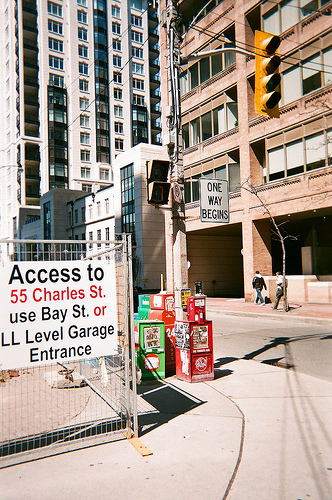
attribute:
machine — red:
[170, 279, 216, 385]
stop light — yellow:
[251, 28, 281, 120]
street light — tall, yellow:
[239, 21, 304, 134]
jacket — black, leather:
[250, 274, 268, 291]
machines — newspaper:
[135, 289, 220, 388]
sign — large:
[24, 257, 123, 387]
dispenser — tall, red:
[176, 289, 220, 383]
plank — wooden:
[124, 430, 152, 455]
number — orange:
[8, 286, 27, 307]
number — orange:
[152, 184, 168, 203]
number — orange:
[164, 323, 177, 341]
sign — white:
[200, 178, 229, 222]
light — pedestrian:
[134, 161, 173, 210]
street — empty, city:
[194, 301, 329, 379]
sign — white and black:
[201, 179, 225, 220]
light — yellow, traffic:
[241, 18, 291, 126]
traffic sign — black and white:
[195, 176, 229, 223]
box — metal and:
[185, 309, 219, 407]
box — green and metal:
[143, 330, 168, 407]